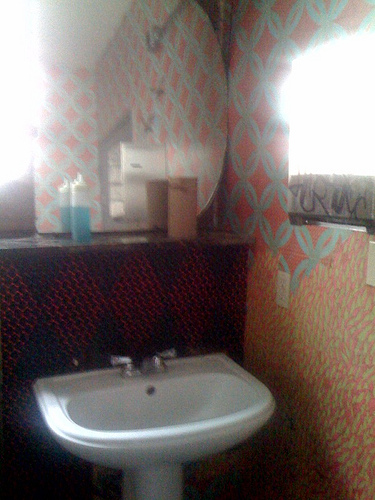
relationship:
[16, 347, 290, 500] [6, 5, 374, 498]
sink in bathroom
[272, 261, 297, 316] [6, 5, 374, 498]
outlet in bathroom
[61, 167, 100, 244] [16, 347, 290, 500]
bottle above sink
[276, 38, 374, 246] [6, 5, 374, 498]
mirror in bathroom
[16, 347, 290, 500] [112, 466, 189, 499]
sink has a base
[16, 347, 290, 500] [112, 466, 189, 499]
sink has pedestal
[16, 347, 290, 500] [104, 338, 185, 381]
sink has faucets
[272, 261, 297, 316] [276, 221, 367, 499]
socket on wall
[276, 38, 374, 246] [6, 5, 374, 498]
mirror in toilet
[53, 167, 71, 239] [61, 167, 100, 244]
reflection on bottle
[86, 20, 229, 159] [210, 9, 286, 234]
reflection of wall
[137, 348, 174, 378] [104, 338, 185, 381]
faucet color silver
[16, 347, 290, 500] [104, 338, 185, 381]
sink has handle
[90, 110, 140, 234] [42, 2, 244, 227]
door reflected in mirror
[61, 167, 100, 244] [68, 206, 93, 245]
bottle containing blue liquid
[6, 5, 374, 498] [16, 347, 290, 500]
bathroom has a sink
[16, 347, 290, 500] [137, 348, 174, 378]
sink has a faucet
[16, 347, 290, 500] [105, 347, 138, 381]
sink has a handle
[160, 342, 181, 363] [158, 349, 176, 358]
handle on handle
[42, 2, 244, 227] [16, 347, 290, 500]
mirror on top sink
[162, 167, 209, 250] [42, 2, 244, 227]
tube reflection on mirror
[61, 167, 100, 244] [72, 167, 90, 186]
bottle has cap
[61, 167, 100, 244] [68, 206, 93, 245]
bottle has blue liquid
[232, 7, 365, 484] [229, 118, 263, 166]
paper patterned diamond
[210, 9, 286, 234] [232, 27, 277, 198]
wall with flowers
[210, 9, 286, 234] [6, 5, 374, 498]
wall of bathroom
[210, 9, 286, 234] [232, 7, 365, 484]
wall covered with paper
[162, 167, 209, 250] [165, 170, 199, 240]
tube of paper roll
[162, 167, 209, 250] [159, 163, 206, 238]
tube of toilet paper